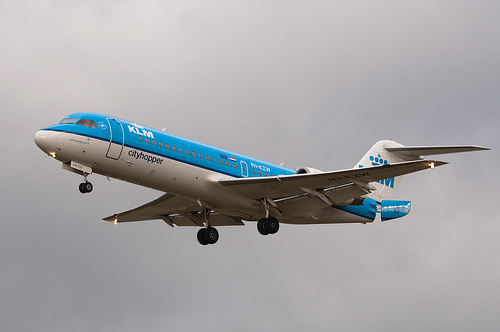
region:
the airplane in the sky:
[32, 111, 491, 245]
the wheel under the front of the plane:
[77, 180, 92, 193]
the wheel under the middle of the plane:
[195, 225, 218, 245]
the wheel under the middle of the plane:
[255, 216, 278, 236]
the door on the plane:
[105, 117, 125, 160]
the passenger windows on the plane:
[137, 134, 274, 178]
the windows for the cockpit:
[54, 117, 98, 130]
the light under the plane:
[48, 150, 56, 159]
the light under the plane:
[429, 161, 435, 171]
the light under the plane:
[112, 216, 118, 226]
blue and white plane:
[39, 75, 444, 264]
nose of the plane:
[3, 99, 103, 173]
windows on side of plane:
[126, 119, 253, 175]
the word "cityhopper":
[118, 146, 186, 176]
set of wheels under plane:
[248, 203, 293, 246]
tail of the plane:
[346, 119, 456, 209]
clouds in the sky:
[154, 8, 314, 100]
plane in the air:
[16, 61, 463, 278]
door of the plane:
[93, 108, 138, 174]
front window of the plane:
[56, 108, 111, 138]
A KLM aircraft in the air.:
[30, 105, 490, 250]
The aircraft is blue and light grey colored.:
[35, 110, 485, 237]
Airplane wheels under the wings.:
[195, 210, 285, 245]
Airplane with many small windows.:
[135, 130, 235, 170]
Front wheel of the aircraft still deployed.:
[71, 171, 97, 197]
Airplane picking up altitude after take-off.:
[25, 105, 495, 250]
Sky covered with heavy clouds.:
[10, 5, 485, 110]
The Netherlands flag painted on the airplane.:
[225, 150, 235, 160]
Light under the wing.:
[105, 210, 120, 225]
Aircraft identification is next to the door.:
[244, 160, 276, 173]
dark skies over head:
[211, 62, 388, 117]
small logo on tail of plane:
[370, 199, 423, 219]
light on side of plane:
[425, 157, 458, 181]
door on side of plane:
[236, 157, 254, 185]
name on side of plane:
[121, 113, 167, 145]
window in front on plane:
[56, 115, 87, 127]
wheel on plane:
[59, 163, 118, 209]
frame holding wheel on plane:
[64, 148, 104, 180]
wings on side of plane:
[234, 155, 469, 190]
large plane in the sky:
[36, 109, 483, 238]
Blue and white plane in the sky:
[28, 78, 474, 283]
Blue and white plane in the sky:
[66, 111, 443, 229]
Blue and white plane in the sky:
[166, 137, 400, 235]